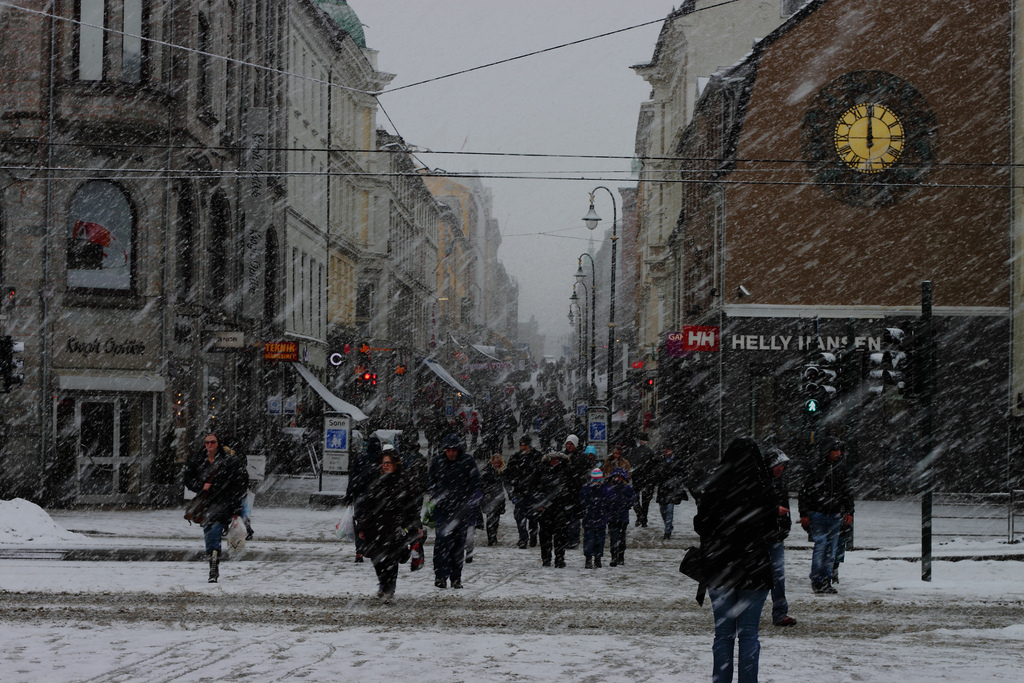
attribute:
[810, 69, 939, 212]
clock — black, yellow, white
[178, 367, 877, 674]
people — dark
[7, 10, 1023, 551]
building — red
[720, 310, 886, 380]
sign — white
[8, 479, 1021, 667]
snow — white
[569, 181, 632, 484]
street light — old, grey day, cane shaped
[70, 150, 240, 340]
window — rounded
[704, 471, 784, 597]
jacket — black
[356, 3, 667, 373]
sky — cloudy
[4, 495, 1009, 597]
drift — large